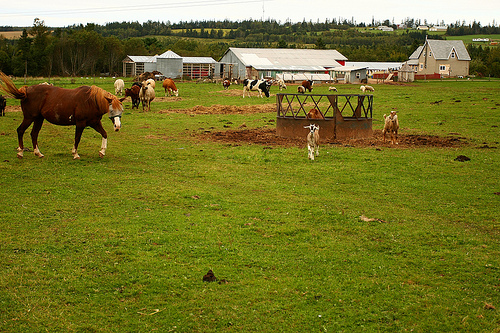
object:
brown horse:
[3, 80, 122, 157]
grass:
[12, 157, 122, 169]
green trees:
[2, 21, 494, 76]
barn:
[117, 36, 401, 82]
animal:
[358, 106, 413, 158]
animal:
[123, 82, 142, 109]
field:
[3, 80, 495, 328]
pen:
[268, 87, 378, 140]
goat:
[303, 122, 322, 161]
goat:
[380, 108, 401, 146]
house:
[396, 40, 471, 77]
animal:
[296, 117, 335, 159]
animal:
[241, 77, 271, 97]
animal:
[3, 75, 123, 162]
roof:
[426, 37, 471, 61]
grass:
[240, 174, 466, 311]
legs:
[70, 113, 83, 160]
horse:
[5, 77, 124, 159]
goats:
[302, 122, 322, 160]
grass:
[2, 78, 497, 330]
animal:
[159, 76, 181, 98]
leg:
[88, 120, 109, 159]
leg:
[67, 124, 86, 161]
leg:
[29, 119, 45, 159]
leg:
[13, 113, 33, 158]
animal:
[136, 79, 155, 111]